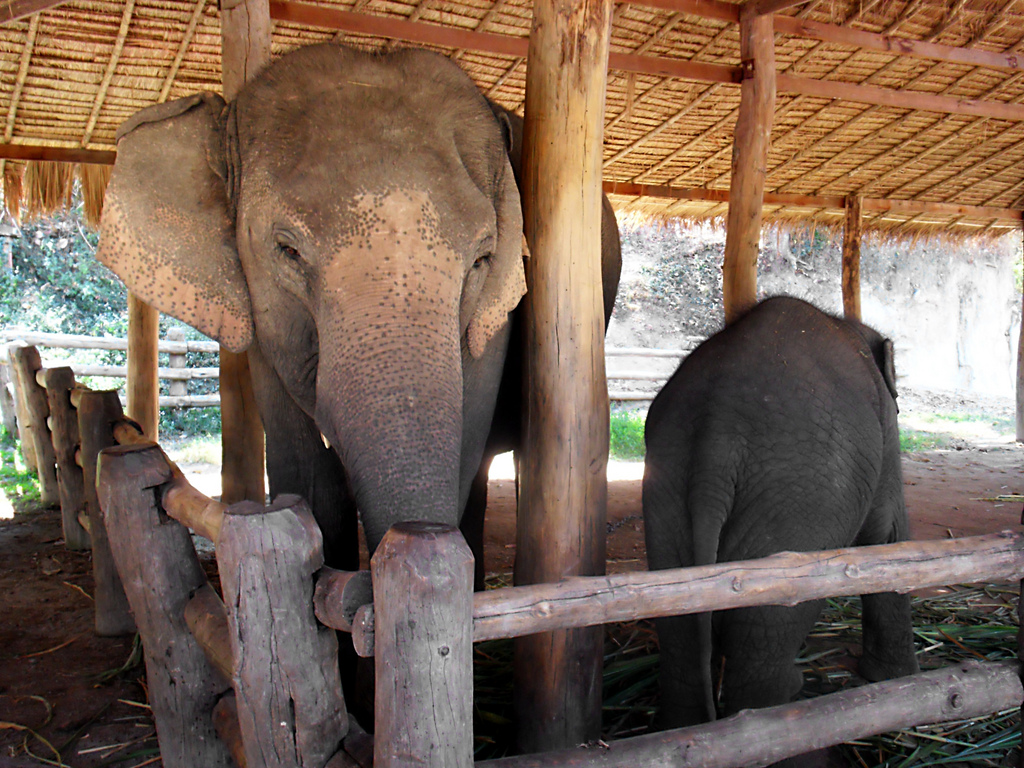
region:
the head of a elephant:
[187, 81, 614, 454]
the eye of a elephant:
[226, 204, 345, 318]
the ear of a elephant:
[60, 72, 352, 336]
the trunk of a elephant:
[313, 280, 536, 598]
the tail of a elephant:
[647, 420, 809, 711]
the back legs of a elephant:
[616, 453, 861, 738]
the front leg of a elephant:
[817, 470, 953, 704]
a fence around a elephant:
[73, 226, 813, 751]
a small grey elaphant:
[571, 232, 1001, 748]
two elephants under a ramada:
[3, 0, 942, 690]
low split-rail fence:
[9, 338, 1018, 759]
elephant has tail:
[637, 291, 913, 719]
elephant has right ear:
[94, 35, 626, 583]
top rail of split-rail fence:
[352, 515, 1021, 645]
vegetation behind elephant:
[0, 35, 621, 434]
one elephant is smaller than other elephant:
[93, 31, 918, 680]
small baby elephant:
[641, 290, 913, 734]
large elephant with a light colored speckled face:
[91, 32, 623, 764]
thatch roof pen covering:
[3, 0, 1022, 231]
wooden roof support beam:
[512, 0, 614, 751]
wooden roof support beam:
[215, 2, 272, 503]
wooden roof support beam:
[126, 287, 161, 444]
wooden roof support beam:
[721, 9, 778, 317]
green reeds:
[584, 575, 1021, 765]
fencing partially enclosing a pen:
[0, 323, 1022, 766]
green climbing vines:
[0, 177, 226, 434]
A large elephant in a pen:
[117, 29, 618, 754]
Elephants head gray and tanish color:
[91, 28, 537, 507]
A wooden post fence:
[78, 408, 512, 745]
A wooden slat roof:
[622, 22, 949, 201]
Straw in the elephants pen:
[900, 582, 989, 656]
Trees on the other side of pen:
[13, 228, 116, 333]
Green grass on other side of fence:
[609, 396, 645, 469]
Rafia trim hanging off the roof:
[5, 151, 95, 213]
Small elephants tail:
[667, 426, 759, 712]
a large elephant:
[98, 45, 653, 750]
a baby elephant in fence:
[587, 228, 945, 766]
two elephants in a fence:
[19, 6, 1018, 763]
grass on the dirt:
[577, 550, 1018, 765]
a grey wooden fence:
[185, 503, 1017, 766]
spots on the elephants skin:
[345, 85, 466, 395]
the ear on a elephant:
[73, 60, 301, 389]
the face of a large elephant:
[220, 38, 512, 440]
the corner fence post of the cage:
[364, 518, 478, 766]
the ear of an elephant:
[93, 83, 256, 349]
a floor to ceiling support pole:
[523, 2, 613, 764]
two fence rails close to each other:
[305, 568, 385, 667]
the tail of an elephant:
[693, 609, 719, 727]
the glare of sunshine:
[863, 225, 1022, 447]